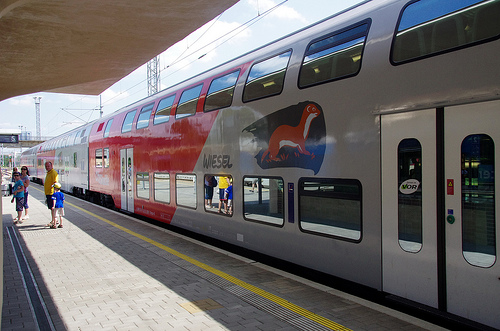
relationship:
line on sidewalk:
[28, 178, 350, 330] [0, 179, 443, 327]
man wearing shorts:
[43, 158, 60, 230] [44, 192, 55, 209]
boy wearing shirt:
[50, 181, 66, 229] [50, 192, 66, 209]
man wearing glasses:
[7, 172, 26, 228] [11, 174, 23, 180]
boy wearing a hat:
[50, 181, 66, 229] [53, 180, 64, 190]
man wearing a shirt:
[43, 158, 60, 230] [44, 172, 60, 196]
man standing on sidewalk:
[43, 158, 60, 230] [0, 179, 443, 327]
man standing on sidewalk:
[7, 172, 26, 228] [0, 179, 443, 327]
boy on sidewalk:
[50, 181, 66, 229] [0, 179, 443, 327]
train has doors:
[16, 0, 497, 330] [378, 97, 497, 330]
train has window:
[16, 0, 497, 330] [389, 1, 499, 68]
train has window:
[16, 0, 497, 330] [294, 16, 372, 90]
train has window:
[16, 0, 497, 330] [241, 49, 294, 105]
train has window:
[16, 0, 497, 330] [201, 65, 241, 115]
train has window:
[16, 0, 497, 330] [176, 83, 202, 121]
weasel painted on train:
[260, 102, 323, 167] [16, 0, 497, 330]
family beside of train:
[7, 160, 65, 232] [16, 0, 497, 330]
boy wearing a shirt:
[50, 181, 66, 229] [50, 192, 66, 209]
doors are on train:
[378, 97, 497, 330] [16, 0, 497, 330]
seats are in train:
[300, 220, 361, 241] [16, 0, 497, 330]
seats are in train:
[242, 213, 281, 226] [16, 0, 497, 330]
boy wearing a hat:
[50, 181, 66, 229] [51, 181, 63, 188]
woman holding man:
[10, 165, 32, 220] [10, 172, 25, 225]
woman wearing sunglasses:
[10, 165, 32, 220] [19, 167, 27, 172]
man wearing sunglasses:
[7, 172, 26, 228] [19, 167, 27, 172]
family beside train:
[7, 160, 65, 232] [16, 0, 497, 330]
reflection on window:
[204, 174, 232, 217] [202, 171, 235, 216]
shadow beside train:
[27, 178, 447, 329] [16, 0, 497, 330]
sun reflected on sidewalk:
[3, 185, 227, 328] [0, 179, 443, 327]